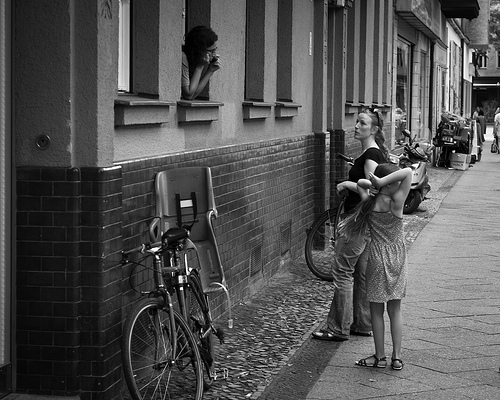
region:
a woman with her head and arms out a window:
[180, 12, 226, 125]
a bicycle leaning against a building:
[124, 157, 236, 397]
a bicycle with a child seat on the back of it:
[119, 158, 236, 398]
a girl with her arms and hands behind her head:
[351, 159, 433, 379]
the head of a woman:
[350, 101, 389, 146]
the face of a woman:
[351, 113, 371, 140]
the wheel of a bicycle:
[299, 207, 338, 282]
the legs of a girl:
[366, 283, 408, 355]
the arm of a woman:
[184, 57, 207, 102]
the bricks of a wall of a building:
[225, 172, 288, 247]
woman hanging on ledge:
[169, 29, 229, 126]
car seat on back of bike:
[156, 161, 236, 287]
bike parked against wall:
[122, 249, 236, 375]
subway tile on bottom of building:
[214, 164, 302, 258]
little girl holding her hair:
[350, 162, 414, 324]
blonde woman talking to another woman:
[348, 100, 374, 289]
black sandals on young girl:
[347, 354, 432, 398]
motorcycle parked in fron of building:
[410, 143, 432, 215]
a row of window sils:
[125, 92, 405, 118]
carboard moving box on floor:
[453, 145, 470, 181]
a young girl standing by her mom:
[348, 160, 420, 377]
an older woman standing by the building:
[308, 108, 380, 348]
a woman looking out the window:
[180, 22, 221, 98]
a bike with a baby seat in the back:
[112, 158, 239, 393]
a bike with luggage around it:
[433, 108, 472, 174]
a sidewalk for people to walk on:
[247, 137, 499, 397]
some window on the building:
[118, 5, 293, 126]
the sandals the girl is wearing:
[353, 343, 408, 375]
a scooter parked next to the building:
[388, 129, 432, 206]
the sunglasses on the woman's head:
[356, 99, 385, 127]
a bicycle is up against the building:
[117, 173, 275, 399]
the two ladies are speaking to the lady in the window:
[302, 92, 435, 377]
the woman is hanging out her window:
[157, 18, 252, 132]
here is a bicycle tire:
[301, 201, 355, 289]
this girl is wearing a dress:
[362, 197, 412, 310]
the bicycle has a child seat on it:
[143, 161, 234, 248]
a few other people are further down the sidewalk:
[469, 102, 499, 153]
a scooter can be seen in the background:
[398, 125, 434, 197]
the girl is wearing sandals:
[351, 354, 409, 370]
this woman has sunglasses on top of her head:
[348, 96, 390, 126]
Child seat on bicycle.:
[146, 162, 234, 292]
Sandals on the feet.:
[352, 347, 408, 374]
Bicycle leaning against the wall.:
[109, 165, 228, 395]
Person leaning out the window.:
[180, 18, 224, 103]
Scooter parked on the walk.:
[395, 127, 437, 214]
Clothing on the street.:
[442, 105, 484, 169]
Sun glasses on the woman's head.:
[350, 103, 386, 150]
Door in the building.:
[312, 0, 352, 253]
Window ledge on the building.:
[115, 90, 175, 130]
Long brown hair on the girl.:
[350, 157, 413, 379]